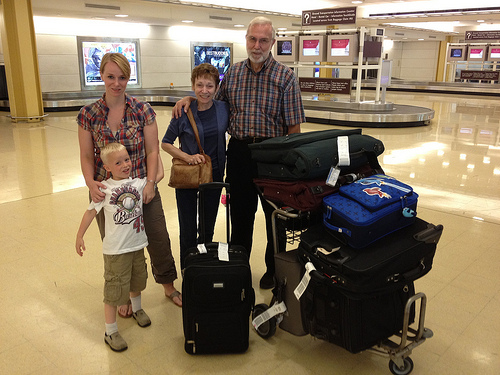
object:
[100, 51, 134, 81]
blond hair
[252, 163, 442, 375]
cart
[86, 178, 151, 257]
shirt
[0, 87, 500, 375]
floor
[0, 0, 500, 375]
airport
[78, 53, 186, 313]
mom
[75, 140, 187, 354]
young boy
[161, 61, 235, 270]
lady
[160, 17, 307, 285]
an older couple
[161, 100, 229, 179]
blue outfit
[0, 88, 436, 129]
baggage claim area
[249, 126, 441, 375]
pile of luggage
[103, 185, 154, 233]
baseball design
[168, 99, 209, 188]
brown purse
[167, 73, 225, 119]
arm around the woman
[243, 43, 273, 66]
man has facial hair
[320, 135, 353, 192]
long tag on luggage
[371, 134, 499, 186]
lights reflected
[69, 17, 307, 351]
family of four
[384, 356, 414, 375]
luggage on wheels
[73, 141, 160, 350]
little boy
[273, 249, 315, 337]
gray baggage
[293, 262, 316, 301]
brown and white sign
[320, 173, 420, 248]
tiny blue luggage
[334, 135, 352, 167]
white baggage claim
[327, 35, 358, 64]
baggage claim monito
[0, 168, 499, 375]
beige tiled floor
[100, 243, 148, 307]
boy's shorts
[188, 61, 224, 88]
woman's hair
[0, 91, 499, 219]
reflecting on floor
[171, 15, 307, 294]
an older man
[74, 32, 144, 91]
shiny baggage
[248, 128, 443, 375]
cart with luggage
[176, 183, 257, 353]
black luggage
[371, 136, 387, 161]
tiny wheel